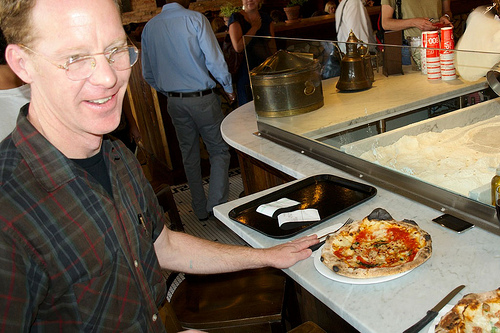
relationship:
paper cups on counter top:
[409, 31, 462, 87] [222, 40, 498, 140]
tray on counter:
[228, 172, 379, 239] [213, 175, 499, 331]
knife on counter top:
[402, 284, 465, 332] [211, 169, 498, 331]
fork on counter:
[309, 216, 350, 240] [348, 282, 406, 324]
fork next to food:
[309, 216, 350, 240] [318, 215, 432, 278]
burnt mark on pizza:
[331, 264, 340, 274] [313, 205, 437, 285]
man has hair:
[0, 0, 322, 331] [3, 5, 35, 55]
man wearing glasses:
[0, 3, 314, 331] [16, 44, 138, 81]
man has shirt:
[0, 0, 322, 331] [5, 104, 172, 326]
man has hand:
[0, 3, 314, 331] [161, 237, 322, 271]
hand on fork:
[161, 237, 322, 271] [251, 194, 368, 274]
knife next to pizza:
[402, 284, 465, 332] [433, 286, 498, 330]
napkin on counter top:
[294, 223, 347, 251] [205, 43, 497, 330]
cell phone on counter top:
[431, 211, 476, 235] [211, 169, 498, 331]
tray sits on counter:
[228, 172, 379, 239] [213, 175, 499, 331]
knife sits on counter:
[402, 284, 465, 332] [213, 175, 499, 331]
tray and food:
[228, 172, 379, 239] [318, 215, 432, 278]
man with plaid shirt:
[0, 3, 314, 331] [4, 130, 168, 329]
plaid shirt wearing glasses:
[4, 130, 168, 329] [22, 35, 142, 80]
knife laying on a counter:
[405, 274, 465, 331] [372, 276, 438, 318]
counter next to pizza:
[372, 276, 438, 318] [450, 284, 498, 331]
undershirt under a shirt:
[64, 151, 136, 198] [36, 131, 194, 328]